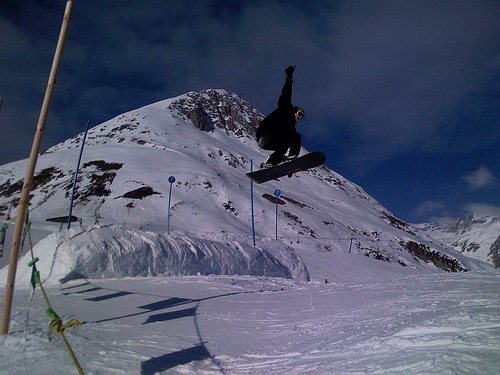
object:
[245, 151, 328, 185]
snowboard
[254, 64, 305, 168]
man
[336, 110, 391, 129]
air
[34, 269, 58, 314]
rope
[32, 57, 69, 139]
pole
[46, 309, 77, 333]
flag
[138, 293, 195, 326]
shadow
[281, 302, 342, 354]
snow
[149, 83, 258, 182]
mountain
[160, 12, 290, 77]
sky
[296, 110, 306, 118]
sunglasses